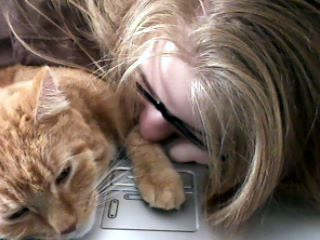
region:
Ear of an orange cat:
[21, 64, 65, 120]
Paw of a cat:
[130, 144, 179, 208]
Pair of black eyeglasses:
[121, 68, 223, 156]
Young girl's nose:
[137, 104, 170, 138]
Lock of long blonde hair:
[205, 55, 285, 228]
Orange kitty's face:
[0, 140, 99, 236]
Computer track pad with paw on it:
[99, 186, 197, 229]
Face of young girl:
[128, 32, 240, 146]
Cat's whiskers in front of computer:
[77, 130, 136, 212]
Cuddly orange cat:
[0, 64, 186, 238]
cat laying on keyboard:
[0, 61, 190, 237]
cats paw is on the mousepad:
[119, 113, 183, 205]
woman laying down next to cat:
[0, 11, 314, 231]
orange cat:
[0, 59, 182, 235]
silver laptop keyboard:
[22, 133, 310, 229]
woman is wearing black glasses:
[124, 73, 211, 156]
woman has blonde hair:
[67, 9, 296, 218]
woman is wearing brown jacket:
[0, 0, 106, 70]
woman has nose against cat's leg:
[106, 72, 190, 146]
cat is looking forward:
[3, 154, 76, 208]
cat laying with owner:
[0, 102, 109, 226]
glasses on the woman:
[135, 95, 201, 145]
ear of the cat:
[26, 74, 69, 133]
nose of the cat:
[54, 204, 79, 232]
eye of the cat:
[52, 158, 84, 195]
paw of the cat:
[149, 175, 186, 216]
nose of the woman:
[140, 110, 167, 149]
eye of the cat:
[2, 200, 34, 222]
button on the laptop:
[103, 192, 121, 219]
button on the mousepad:
[113, 168, 137, 188]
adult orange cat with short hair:
[2, 62, 200, 238]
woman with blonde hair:
[62, 2, 318, 236]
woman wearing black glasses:
[78, 1, 319, 218]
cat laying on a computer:
[4, 63, 188, 239]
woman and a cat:
[4, 2, 314, 238]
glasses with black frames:
[129, 76, 219, 156]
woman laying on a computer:
[111, 1, 319, 236]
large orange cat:
[2, 64, 191, 238]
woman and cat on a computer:
[0, 5, 303, 238]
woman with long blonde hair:
[56, 1, 317, 232]